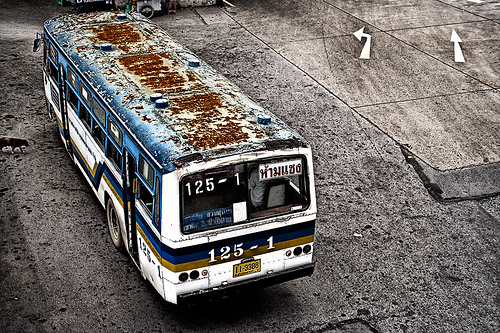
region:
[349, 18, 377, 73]
This a turn left sign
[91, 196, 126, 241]
This is a wheel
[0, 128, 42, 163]
This is an animal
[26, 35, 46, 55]
This is a rearview mirror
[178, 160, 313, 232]
This is a rear window pane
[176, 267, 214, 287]
These are indicator lights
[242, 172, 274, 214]
Thios is a person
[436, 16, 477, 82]
this is a road sign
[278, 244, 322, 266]
This are indicator lights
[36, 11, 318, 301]
This is a bus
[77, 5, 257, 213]
The top of the bus is rusted.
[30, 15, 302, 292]
The bus is blue.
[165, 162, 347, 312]
The front of the bus is white.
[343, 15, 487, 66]
The arrows are white.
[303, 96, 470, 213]
The ground is concrete.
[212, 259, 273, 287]
The license is yellow.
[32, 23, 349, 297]
The bus is old.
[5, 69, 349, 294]
The bus is parked.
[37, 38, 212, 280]
The bus has gold and blue stripes.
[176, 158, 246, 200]
The nunbers are white.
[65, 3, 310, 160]
the top of the bus is rusty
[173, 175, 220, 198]
the number is 125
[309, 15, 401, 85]
arrow pointing to the left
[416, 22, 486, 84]
arrow pointing ahead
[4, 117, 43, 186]
a dog walking towards the bus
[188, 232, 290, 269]
the numbers are white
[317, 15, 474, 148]
the street is dirty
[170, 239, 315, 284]
the headlights are off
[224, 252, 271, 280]
the license plate is yellow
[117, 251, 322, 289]
the bottom of the bus is white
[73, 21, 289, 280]
this is a bus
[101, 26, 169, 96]
the upper part is old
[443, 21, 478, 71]
this is a arrow pointer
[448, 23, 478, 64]
the arrow pointer is white in color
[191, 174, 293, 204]
this is the emergency door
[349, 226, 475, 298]
this is the road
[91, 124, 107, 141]
this is the window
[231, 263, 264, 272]
this is the number plate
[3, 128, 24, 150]
this is a dog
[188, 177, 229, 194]
this is a writing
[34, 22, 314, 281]
old dirty city bus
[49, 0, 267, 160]
dead brown leaves on city bus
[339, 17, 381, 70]
crooked white arrow in concrete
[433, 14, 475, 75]
straight white arrow in concrete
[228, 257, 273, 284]
yellow license plate on rear of bus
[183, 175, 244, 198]
bus number 125-1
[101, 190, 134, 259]
round black rubber bus tire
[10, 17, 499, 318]
flat gray concrete parking area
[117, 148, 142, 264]
rear door to city bus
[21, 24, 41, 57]
rear view mirror on side of bus